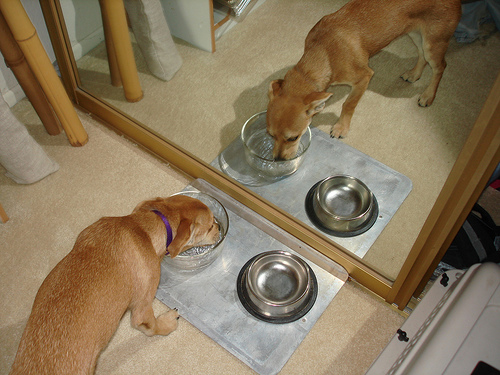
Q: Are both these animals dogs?
A: Yes, all the animals are dogs.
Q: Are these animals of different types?
A: No, all the animals are dogs.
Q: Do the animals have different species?
A: No, all the animals are dogs.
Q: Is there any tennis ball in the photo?
A: No, there are no tennis balls.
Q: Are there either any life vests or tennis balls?
A: No, there are no tennis balls or life vests.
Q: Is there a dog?
A: Yes, there is a dog.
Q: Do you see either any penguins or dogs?
A: Yes, there is a dog.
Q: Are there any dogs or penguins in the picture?
A: Yes, there is a dog.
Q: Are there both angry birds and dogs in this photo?
A: No, there is a dog but no angry birds.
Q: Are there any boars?
A: No, there are no boars.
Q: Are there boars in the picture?
A: No, there are no boars.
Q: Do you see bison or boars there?
A: No, there are no boars or bison.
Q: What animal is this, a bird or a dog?
A: This is a dog.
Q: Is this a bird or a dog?
A: This is a dog.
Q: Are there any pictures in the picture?
A: No, there are no pictures.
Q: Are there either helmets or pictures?
A: No, there are no pictures or helmets.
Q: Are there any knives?
A: No, there are no knives.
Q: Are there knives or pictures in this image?
A: No, there are no knives or pictures.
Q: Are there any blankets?
A: No, there are no blankets.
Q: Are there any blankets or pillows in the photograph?
A: No, there are no blankets or pillows.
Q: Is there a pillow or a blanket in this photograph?
A: No, there are no blankets or pillows.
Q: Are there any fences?
A: No, there are no fences.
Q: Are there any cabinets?
A: No, there are no cabinets.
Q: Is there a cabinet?
A: No, there are no cabinets.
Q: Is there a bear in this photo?
A: No, there are no bears.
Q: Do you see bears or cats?
A: No, there are no bears or cats.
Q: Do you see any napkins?
A: No, there are no napkins.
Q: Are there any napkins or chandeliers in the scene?
A: No, there are no napkins or chandeliers.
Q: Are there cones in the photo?
A: No, there are no cones.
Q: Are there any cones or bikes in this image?
A: No, there are no cones or bikes.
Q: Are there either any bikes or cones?
A: No, there are no cones or bikes.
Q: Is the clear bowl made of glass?
A: Yes, the bowl is made of glass.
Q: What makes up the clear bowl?
A: The bowl is made of glass.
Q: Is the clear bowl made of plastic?
A: No, the bowl is made of glass.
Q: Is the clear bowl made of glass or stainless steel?
A: The bowl is made of glass.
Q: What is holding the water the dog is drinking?
A: The bowl is holding the water.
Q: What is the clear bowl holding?
A: The bowl is holding the water.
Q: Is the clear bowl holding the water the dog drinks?
A: Yes, the bowl is holding the water.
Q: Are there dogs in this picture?
A: Yes, there is a dog.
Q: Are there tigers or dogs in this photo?
A: Yes, there is a dog.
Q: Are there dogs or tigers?
A: Yes, there is a dog.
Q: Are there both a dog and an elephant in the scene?
A: No, there is a dog but no elephants.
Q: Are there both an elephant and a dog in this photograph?
A: No, there is a dog but no elephants.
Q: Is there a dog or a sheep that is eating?
A: Yes, the dog is eating.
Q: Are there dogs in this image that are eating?
A: Yes, there is a dog that is eating.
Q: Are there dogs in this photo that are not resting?
A: Yes, there is a dog that is eating.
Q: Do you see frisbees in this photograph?
A: No, there are no frisbees.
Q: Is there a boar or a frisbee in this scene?
A: No, there are no frisbees or boars.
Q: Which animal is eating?
A: The animal is a dog.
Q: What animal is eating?
A: The animal is a dog.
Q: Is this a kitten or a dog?
A: This is a dog.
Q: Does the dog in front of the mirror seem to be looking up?
A: No, the dog is eating.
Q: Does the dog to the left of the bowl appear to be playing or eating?
A: The dog is eating.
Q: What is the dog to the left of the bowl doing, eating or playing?
A: The dog is eating.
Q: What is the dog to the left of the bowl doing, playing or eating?
A: The dog is eating.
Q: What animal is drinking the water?
A: The dog is drinking the water.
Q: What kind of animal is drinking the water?
A: The animal is a dog.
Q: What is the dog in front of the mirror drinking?
A: The dog is drinking water.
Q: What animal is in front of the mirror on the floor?
A: The dog is in front of the mirror.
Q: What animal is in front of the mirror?
A: The dog is in front of the mirror.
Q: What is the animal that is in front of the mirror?
A: The animal is a dog.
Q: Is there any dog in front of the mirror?
A: Yes, there is a dog in front of the mirror.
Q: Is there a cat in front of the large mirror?
A: No, there is a dog in front of the mirror.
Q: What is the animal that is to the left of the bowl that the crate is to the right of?
A: The animal is a dog.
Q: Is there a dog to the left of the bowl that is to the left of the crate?
A: Yes, there is a dog to the left of the bowl.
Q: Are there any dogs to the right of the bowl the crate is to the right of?
A: No, the dog is to the left of the bowl.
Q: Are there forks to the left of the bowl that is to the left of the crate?
A: No, there is a dog to the left of the bowl.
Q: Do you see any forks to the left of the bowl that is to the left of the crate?
A: No, there is a dog to the left of the bowl.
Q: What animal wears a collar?
A: The dog wears a collar.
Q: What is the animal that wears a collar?
A: The animal is a dog.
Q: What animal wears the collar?
A: The animal is a dog.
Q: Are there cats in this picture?
A: No, there are no cats.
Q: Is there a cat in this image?
A: No, there are no cats.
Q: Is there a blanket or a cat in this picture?
A: No, there are no cats or blankets.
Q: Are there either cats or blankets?
A: No, there are no cats or blankets.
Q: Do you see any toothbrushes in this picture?
A: No, there are no toothbrushes.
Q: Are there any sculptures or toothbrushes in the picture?
A: No, there are no toothbrushes or sculptures.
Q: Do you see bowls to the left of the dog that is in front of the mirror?
A: No, the bowl is to the right of the dog.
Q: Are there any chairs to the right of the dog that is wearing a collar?
A: No, there is a bowl to the right of the dog.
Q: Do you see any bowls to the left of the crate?
A: Yes, there is a bowl to the left of the crate.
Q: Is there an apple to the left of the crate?
A: No, there is a bowl to the left of the crate.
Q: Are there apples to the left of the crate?
A: No, there is a bowl to the left of the crate.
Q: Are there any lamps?
A: No, there are no lamps.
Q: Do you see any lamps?
A: No, there are no lamps.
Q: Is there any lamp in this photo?
A: No, there are no lamps.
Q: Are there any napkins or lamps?
A: No, there are no lamps or napkins.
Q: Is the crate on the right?
A: Yes, the crate is on the right of the image.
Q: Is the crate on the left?
A: No, the crate is on the right of the image.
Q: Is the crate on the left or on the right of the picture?
A: The crate is on the right of the image.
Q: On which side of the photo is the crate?
A: The crate is on the right of the image.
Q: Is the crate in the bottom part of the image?
A: Yes, the crate is in the bottom of the image.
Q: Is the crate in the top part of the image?
A: No, the crate is in the bottom of the image.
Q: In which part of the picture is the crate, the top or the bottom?
A: The crate is in the bottom of the image.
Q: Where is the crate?
A: The crate is on the floor.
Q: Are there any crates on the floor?
A: Yes, there is a crate on the floor.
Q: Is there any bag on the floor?
A: No, there is a crate on the floor.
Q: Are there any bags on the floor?
A: No, there is a crate on the floor.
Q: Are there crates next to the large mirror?
A: Yes, there is a crate next to the mirror.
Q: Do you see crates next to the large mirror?
A: Yes, there is a crate next to the mirror.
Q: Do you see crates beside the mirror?
A: Yes, there is a crate beside the mirror.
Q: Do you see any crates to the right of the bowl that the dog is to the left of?
A: Yes, there is a crate to the right of the bowl.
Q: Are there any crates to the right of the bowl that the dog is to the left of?
A: Yes, there is a crate to the right of the bowl.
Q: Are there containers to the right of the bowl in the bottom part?
A: No, there is a crate to the right of the bowl.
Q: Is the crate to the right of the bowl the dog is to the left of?
A: Yes, the crate is to the right of the bowl.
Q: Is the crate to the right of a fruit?
A: No, the crate is to the right of the bowl.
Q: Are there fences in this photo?
A: No, there are no fences.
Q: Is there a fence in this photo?
A: No, there are no fences.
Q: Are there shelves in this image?
A: No, there are no shelves.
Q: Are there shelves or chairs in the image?
A: No, there are no shelves or chairs.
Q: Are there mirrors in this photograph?
A: Yes, there is a mirror.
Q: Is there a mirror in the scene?
A: Yes, there is a mirror.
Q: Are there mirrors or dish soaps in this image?
A: Yes, there is a mirror.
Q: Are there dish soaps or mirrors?
A: Yes, there is a mirror.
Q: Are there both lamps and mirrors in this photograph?
A: No, there is a mirror but no lamps.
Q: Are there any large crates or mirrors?
A: Yes, there is a large mirror.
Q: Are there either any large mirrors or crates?
A: Yes, there is a large mirror.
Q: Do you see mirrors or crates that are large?
A: Yes, the mirror is large.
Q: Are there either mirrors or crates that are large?
A: Yes, the mirror is large.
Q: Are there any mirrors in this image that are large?
A: Yes, there is a large mirror.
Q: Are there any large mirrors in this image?
A: Yes, there is a large mirror.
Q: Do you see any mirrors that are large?
A: Yes, there is a large mirror.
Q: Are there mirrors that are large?
A: Yes, there is a mirror that is large.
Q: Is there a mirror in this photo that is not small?
A: Yes, there is a large mirror.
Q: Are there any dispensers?
A: No, there are no dispensers.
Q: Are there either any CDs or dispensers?
A: No, there are no dispensers or cds.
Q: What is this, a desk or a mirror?
A: This is a mirror.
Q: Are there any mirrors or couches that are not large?
A: No, there is a mirror but it is large.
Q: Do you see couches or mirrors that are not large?
A: No, there is a mirror but it is large.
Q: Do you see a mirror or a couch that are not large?
A: No, there is a mirror but it is large.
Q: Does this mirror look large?
A: Yes, the mirror is large.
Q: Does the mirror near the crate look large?
A: Yes, the mirror is large.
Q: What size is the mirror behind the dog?
A: The mirror is large.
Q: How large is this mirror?
A: The mirror is large.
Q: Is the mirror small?
A: No, the mirror is large.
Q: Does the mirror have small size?
A: No, the mirror is large.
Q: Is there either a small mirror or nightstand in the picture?
A: No, there is a mirror but it is large.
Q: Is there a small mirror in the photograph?
A: No, there is a mirror but it is large.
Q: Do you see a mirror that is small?
A: No, there is a mirror but it is large.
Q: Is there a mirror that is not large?
A: No, there is a mirror but it is large.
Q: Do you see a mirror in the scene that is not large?
A: No, there is a mirror but it is large.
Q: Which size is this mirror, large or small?
A: The mirror is large.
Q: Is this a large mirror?
A: Yes, this is a large mirror.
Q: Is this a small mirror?
A: No, this is a large mirror.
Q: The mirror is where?
A: The mirror is on the floor.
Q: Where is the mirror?
A: The mirror is on the floor.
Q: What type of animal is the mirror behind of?
A: The mirror is behind the dog.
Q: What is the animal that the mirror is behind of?
A: The animal is a dog.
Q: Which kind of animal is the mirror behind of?
A: The mirror is behind the dog.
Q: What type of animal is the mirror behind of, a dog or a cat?
A: The mirror is behind a dog.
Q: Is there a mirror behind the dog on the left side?
A: Yes, there is a mirror behind the dog.